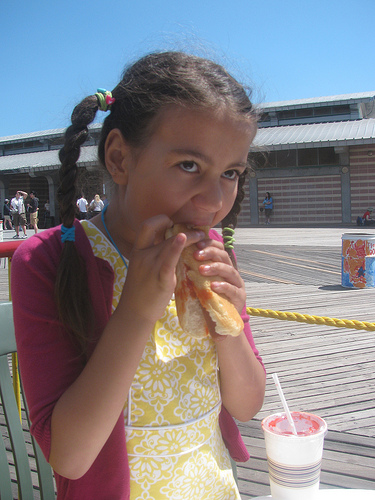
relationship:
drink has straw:
[261, 409, 328, 497] [269, 372, 298, 433]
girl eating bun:
[11, 50, 265, 498] [179, 229, 213, 263]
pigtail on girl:
[38, 90, 111, 253] [69, 44, 270, 292]